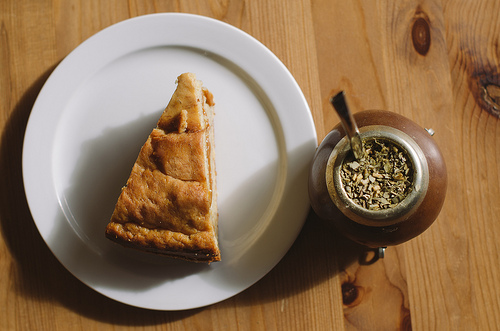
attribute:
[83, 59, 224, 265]
pie — brown, pointy, curved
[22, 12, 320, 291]
plate — white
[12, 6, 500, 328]
table — wood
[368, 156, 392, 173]
seasoning — brown